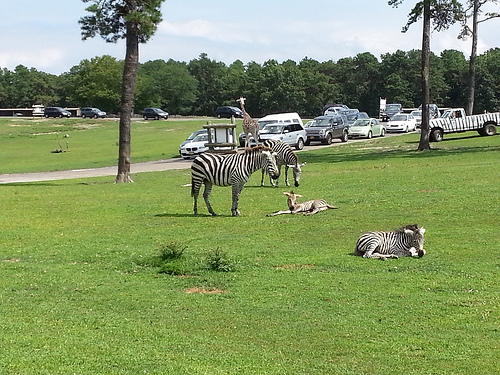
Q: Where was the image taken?
A: It was taken at the zoo.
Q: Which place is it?
A: It is a zoo.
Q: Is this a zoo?
A: Yes, it is a zoo.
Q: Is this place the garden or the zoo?
A: It is the zoo.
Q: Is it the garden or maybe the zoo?
A: It is the zoo.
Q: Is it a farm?
A: No, it is a zoo.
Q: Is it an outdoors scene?
A: Yes, it is outdoors.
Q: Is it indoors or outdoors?
A: It is outdoors.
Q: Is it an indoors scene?
A: No, it is outdoors.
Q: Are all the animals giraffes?
A: No, there are both giraffes and zebras.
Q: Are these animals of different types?
A: Yes, they are giraffes and zebras.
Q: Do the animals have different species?
A: Yes, they are giraffes and zebras.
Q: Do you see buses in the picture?
A: No, there are no buses.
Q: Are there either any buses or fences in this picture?
A: No, there are no buses or fences.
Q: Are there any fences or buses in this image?
A: No, there are no buses or fences.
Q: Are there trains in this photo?
A: No, there are no trains.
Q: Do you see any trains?
A: No, there are no trains.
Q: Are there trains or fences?
A: No, there are no trains or fences.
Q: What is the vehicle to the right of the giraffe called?
A: The vehicle is a car.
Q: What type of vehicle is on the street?
A: The vehicle is a car.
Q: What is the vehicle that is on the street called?
A: The vehicle is a car.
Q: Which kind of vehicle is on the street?
A: The vehicle is a car.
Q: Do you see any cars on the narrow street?
A: Yes, there is a car on the street.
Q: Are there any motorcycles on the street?
A: No, there is a car on the street.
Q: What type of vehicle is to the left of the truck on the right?
A: The vehicle is a car.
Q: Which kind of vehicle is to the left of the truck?
A: The vehicle is a car.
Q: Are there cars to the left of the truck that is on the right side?
A: Yes, there is a car to the left of the truck.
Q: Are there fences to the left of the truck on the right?
A: No, there is a car to the left of the truck.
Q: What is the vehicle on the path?
A: The vehicle is a car.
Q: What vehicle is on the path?
A: The vehicle is a car.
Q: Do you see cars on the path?
A: Yes, there is a car on the path.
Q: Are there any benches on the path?
A: No, there is a car on the path.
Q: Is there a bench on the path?
A: No, there is a car on the path.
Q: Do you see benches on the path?
A: No, there is a car on the path.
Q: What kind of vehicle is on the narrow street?
A: The vehicle is a car.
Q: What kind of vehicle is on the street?
A: The vehicle is a car.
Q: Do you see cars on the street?
A: Yes, there is a car on the street.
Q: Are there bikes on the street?
A: No, there is a car on the street.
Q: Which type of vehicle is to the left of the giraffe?
A: The vehicle is a car.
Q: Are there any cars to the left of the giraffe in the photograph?
A: Yes, there is a car to the left of the giraffe.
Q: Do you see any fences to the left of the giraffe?
A: No, there is a car to the left of the giraffe.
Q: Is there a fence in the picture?
A: No, there are no fences.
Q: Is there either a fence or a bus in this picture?
A: No, there are no fences or buses.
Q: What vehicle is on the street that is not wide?
A: The vehicle is a car.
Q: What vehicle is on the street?
A: The vehicle is a car.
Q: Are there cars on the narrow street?
A: Yes, there is a car on the street.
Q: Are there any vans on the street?
A: No, there is a car on the street.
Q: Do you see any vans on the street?
A: No, there is a car on the street.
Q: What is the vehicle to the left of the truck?
A: The vehicle is a car.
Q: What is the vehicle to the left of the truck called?
A: The vehicle is a car.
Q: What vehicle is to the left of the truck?
A: The vehicle is a car.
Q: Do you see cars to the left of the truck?
A: Yes, there is a car to the left of the truck.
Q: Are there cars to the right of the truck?
A: No, the car is to the left of the truck.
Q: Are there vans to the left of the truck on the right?
A: No, there is a car to the left of the truck.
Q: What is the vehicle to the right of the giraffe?
A: The vehicle is a car.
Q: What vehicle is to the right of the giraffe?
A: The vehicle is a car.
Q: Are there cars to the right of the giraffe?
A: Yes, there is a car to the right of the giraffe.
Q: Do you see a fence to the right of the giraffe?
A: No, there is a car to the right of the giraffe.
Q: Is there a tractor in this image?
A: No, there are no tractors.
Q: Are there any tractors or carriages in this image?
A: No, there are no tractors or carriages.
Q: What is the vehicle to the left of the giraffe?
A: The vehicle is a car.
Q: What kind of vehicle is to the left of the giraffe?
A: The vehicle is a car.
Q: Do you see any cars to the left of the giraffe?
A: Yes, there is a car to the left of the giraffe.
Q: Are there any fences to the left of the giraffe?
A: No, there is a car to the left of the giraffe.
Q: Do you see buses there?
A: No, there are no buses.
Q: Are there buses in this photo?
A: No, there are no buses.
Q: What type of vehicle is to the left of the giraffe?
A: The vehicle is a car.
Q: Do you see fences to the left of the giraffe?
A: No, there is a car to the left of the giraffe.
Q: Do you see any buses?
A: No, there are no buses.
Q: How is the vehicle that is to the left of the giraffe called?
A: The vehicle is a car.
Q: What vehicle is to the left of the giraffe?
A: The vehicle is a car.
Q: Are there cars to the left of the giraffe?
A: Yes, there is a car to the left of the giraffe.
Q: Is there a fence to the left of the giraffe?
A: No, there is a car to the left of the giraffe.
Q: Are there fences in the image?
A: No, there are no fences.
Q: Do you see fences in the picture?
A: No, there are no fences.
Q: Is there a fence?
A: No, there are no fences.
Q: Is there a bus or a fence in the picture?
A: No, there are no fences or buses.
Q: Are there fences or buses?
A: No, there are no fences or buses.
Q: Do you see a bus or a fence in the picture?
A: No, there are no fences or buses.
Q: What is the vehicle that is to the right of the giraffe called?
A: The vehicle is a car.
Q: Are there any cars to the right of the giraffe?
A: Yes, there is a car to the right of the giraffe.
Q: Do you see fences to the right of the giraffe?
A: No, there is a car to the right of the giraffe.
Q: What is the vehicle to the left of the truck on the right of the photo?
A: The vehicle is a car.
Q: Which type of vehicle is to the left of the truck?
A: The vehicle is a car.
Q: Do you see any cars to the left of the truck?
A: Yes, there is a car to the left of the truck.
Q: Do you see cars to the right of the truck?
A: No, the car is to the left of the truck.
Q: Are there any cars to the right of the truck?
A: No, the car is to the left of the truck.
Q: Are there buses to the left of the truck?
A: No, there is a car to the left of the truck.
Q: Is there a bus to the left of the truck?
A: No, there is a car to the left of the truck.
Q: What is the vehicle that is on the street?
A: The vehicle is a car.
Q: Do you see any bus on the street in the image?
A: No, there is a car on the street.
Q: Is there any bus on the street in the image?
A: No, there is a car on the street.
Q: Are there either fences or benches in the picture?
A: No, there are no fences or benches.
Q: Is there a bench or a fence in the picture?
A: No, there are no fences or benches.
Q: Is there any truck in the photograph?
A: Yes, there is a truck.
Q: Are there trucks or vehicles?
A: Yes, there is a truck.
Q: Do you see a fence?
A: No, there are no fences.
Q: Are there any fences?
A: No, there are no fences.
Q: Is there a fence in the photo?
A: No, there are no fences.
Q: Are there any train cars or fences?
A: No, there are no fences or train cars.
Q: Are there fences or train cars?
A: No, there are no fences or train cars.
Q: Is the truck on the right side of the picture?
A: Yes, the truck is on the right of the image.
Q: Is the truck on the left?
A: No, the truck is on the right of the image.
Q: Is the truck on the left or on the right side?
A: The truck is on the right of the image.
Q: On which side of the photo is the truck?
A: The truck is on the right of the image.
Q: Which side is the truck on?
A: The truck is on the right of the image.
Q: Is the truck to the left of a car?
A: No, the truck is to the right of a car.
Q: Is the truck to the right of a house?
A: No, the truck is to the right of a car.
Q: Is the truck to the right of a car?
A: Yes, the truck is to the right of a car.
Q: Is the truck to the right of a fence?
A: No, the truck is to the right of a car.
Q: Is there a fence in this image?
A: No, there are no fences.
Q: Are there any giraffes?
A: Yes, there is a giraffe.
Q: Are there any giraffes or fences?
A: Yes, there is a giraffe.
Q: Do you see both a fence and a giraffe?
A: No, there is a giraffe but no fences.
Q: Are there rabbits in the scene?
A: No, there are no rabbits.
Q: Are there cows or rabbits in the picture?
A: No, there are no rabbits or cows.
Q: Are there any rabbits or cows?
A: No, there are no rabbits or cows.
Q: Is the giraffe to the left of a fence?
A: No, the giraffe is to the left of a car.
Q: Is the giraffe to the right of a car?
A: Yes, the giraffe is to the right of a car.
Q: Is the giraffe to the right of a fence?
A: No, the giraffe is to the right of a car.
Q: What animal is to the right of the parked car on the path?
A: The animal is a giraffe.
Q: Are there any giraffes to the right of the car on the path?
A: Yes, there is a giraffe to the right of the car.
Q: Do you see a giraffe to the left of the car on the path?
A: No, the giraffe is to the right of the car.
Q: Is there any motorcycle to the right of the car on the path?
A: No, there is a giraffe to the right of the car.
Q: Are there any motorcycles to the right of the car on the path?
A: No, there is a giraffe to the right of the car.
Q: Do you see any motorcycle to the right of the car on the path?
A: No, there is a giraffe to the right of the car.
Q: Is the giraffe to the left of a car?
A: No, the giraffe is to the right of a car.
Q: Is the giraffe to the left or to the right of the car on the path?
A: The giraffe is to the right of the car.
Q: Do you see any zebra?
A: Yes, there is a zebra.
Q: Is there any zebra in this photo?
A: Yes, there is a zebra.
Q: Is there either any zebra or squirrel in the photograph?
A: Yes, there is a zebra.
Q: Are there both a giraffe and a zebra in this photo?
A: Yes, there are both a zebra and a giraffe.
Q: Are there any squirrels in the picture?
A: No, there are no squirrels.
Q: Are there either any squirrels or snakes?
A: No, there are no squirrels or snakes.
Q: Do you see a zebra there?
A: Yes, there is a zebra.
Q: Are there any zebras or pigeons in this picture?
A: Yes, there is a zebra.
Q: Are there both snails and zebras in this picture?
A: No, there is a zebra but no snails.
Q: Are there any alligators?
A: No, there are no alligators.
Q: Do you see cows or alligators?
A: No, there are no alligators or cows.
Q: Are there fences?
A: No, there are no fences.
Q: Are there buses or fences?
A: No, there are no fences or buses.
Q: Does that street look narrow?
A: Yes, the street is narrow.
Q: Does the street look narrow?
A: Yes, the street is narrow.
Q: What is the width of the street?
A: The street is narrow.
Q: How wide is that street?
A: The street is narrow.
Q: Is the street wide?
A: No, the street is narrow.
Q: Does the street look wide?
A: No, the street is narrow.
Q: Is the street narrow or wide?
A: The street is narrow.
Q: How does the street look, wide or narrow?
A: The street is narrow.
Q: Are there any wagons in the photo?
A: No, there are no wagons.